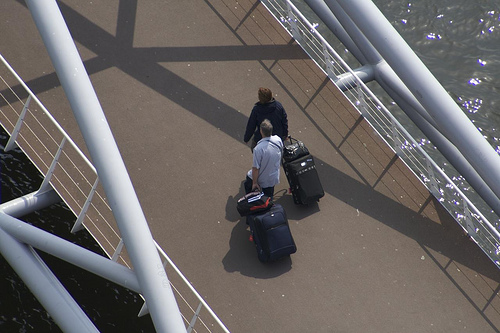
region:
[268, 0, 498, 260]
THIS IS SOME WATER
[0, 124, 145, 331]
THIS IS MORE WATER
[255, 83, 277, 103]
THIS IS HIS HEAD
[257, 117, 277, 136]
THIS IS ANOTHER MAN'S HEAD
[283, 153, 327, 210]
THIS IS HIS SUITCASE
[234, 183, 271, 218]
THIS IS A TOTE BAG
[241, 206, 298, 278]
THIS IS HIS BLACK SUITCASE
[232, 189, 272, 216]
THIS IS A RED AND BLACK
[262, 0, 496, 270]
THIS IS A RAIL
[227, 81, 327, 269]
TWO MEN WITH SUITCASES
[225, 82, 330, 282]
Two people walking on a bridge.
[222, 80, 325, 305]
Two people walking with their luggage.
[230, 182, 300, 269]
Black suitcase with bags on top of it.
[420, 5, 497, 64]
Large body of water below the bridge.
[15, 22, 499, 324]
A large bridge crossing a large body of water.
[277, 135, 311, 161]
Woman's black purse.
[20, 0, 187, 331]
Large white metal poles supporting the bridge.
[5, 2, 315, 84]
Shadows of the bridge structure covering the ground.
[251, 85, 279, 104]
Woman with red hair.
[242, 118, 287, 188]
Man wearing a light blue shirt.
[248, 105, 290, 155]
the head of a man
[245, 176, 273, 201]
the hand of a man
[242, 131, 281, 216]
the arm of a man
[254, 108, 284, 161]
the hair of a man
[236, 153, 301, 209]
the back of a man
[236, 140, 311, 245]
a man with a bag of a man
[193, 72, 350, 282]
a man walking on a bridge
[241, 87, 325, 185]
the back of a man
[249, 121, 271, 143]
the face of a man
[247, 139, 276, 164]
the shoulder of a man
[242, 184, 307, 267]
Man dragging a suitcase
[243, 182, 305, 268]
Man is dragging a suitcase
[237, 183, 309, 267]
Man dragging a black suitcase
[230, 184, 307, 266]
Man is dragging a black suitcase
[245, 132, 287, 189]
Man wearing a shirt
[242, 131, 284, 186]
Man is wearing a shirt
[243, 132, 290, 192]
Man wearing a blue shirt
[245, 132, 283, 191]
Man is wearing a blue shirt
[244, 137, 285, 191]
Man wearing a short sleeved shirt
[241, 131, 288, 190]
Man is wearing a short sleeved shirt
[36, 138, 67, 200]
white metal railing pole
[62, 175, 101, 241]
white metal railing pole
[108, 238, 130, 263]
white metal railing pole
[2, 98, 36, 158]
white metal railing pole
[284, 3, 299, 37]
white metal railing pole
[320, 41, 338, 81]
white metal railing pole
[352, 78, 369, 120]
white metal railing pole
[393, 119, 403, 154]
white metal railing pole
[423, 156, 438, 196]
white metal railing pole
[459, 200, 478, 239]
white metal railing pole